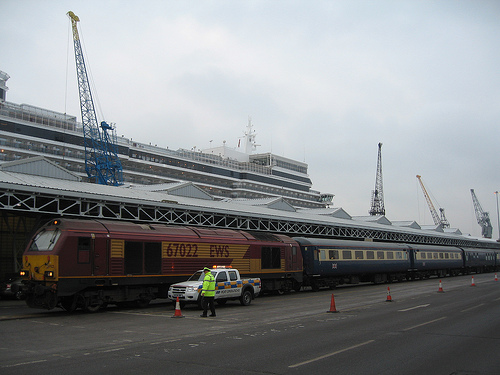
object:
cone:
[325, 292, 340, 312]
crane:
[60, 5, 132, 183]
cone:
[168, 291, 190, 320]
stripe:
[171, 300, 182, 310]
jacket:
[200, 271, 220, 297]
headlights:
[46, 269, 54, 278]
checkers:
[211, 279, 261, 289]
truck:
[165, 263, 263, 306]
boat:
[2, 64, 333, 213]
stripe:
[314, 243, 463, 263]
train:
[19, 208, 498, 316]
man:
[195, 265, 221, 318]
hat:
[200, 264, 210, 274]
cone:
[382, 279, 399, 302]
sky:
[4, 2, 500, 234]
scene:
[0, 0, 500, 375]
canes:
[364, 134, 392, 217]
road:
[0, 317, 500, 375]